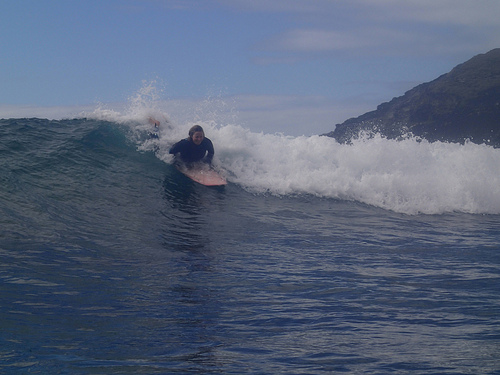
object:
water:
[0, 118, 500, 374]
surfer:
[169, 124, 215, 168]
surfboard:
[175, 161, 228, 188]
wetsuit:
[168, 136, 215, 168]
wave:
[83, 78, 498, 213]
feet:
[145, 114, 162, 129]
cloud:
[285, 27, 375, 54]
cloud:
[371, 2, 500, 29]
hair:
[188, 125, 206, 137]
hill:
[310, 45, 500, 149]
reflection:
[166, 169, 227, 374]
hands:
[176, 160, 213, 173]